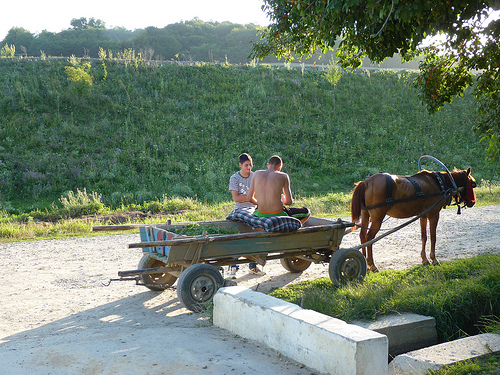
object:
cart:
[85, 211, 367, 295]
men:
[229, 151, 257, 210]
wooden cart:
[115, 208, 366, 317]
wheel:
[329, 249, 367, 289]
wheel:
[281, 251, 313, 274]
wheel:
[140, 256, 179, 289]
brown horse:
[351, 165, 474, 270]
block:
[211, 284, 390, 371]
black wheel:
[182, 263, 226, 308]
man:
[245, 155, 310, 225]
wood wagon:
[80, 218, 385, 306]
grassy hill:
[2, 57, 499, 237]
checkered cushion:
[227, 207, 303, 233]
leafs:
[440, 109, 452, 133]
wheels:
[122, 245, 372, 326]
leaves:
[483, 130, 495, 162]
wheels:
[134, 249, 369, 315]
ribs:
[398, 175, 409, 194]